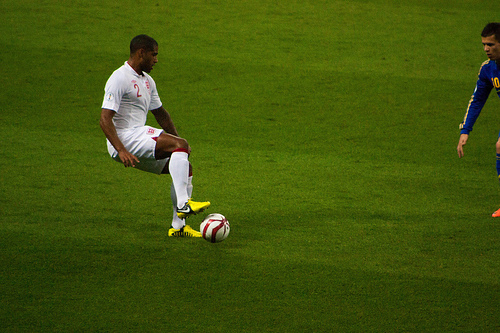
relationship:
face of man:
[149, 49, 160, 68] [95, 32, 214, 241]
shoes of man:
[169, 197, 211, 237] [95, 32, 214, 241]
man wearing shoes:
[95, 32, 214, 241] [169, 197, 211, 237]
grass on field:
[2, 0, 499, 332] [24, 23, 459, 311]